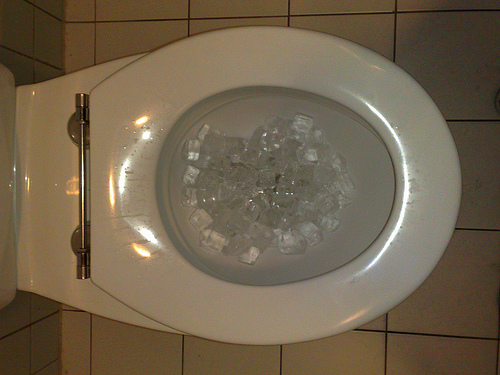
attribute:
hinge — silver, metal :
[72, 90, 89, 142]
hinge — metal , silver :
[71, 237, 91, 280]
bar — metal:
[76, 123, 87, 244]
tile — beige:
[387, 333, 495, 369]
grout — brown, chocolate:
[378, 332, 390, 373]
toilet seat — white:
[90, 23, 463, 345]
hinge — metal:
[71, 89, 91, 279]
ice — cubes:
[248, 133, 312, 203]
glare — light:
[119, 214, 164, 259]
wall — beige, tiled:
[12, 311, 57, 371]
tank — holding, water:
[0, 66, 21, 311]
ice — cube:
[252, 195, 302, 245]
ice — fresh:
[269, 173, 329, 228]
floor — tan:
[409, 257, 489, 354]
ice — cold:
[273, 225, 313, 246]